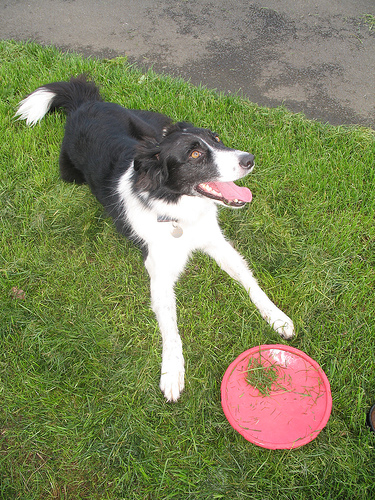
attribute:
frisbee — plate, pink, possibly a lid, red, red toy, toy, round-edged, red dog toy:
[223, 343, 331, 453]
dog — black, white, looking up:
[23, 77, 297, 403]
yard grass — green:
[268, 110, 364, 223]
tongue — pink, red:
[212, 182, 250, 203]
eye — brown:
[202, 157, 215, 167]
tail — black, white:
[14, 81, 103, 126]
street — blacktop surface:
[2, 7, 373, 123]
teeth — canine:
[200, 191, 249, 206]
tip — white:
[13, 92, 56, 124]